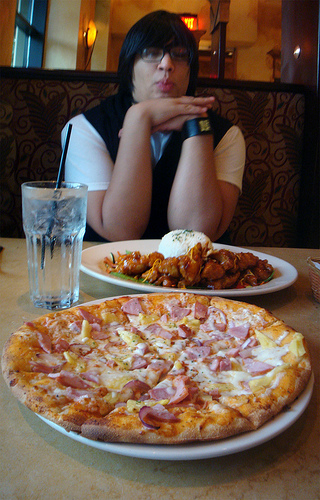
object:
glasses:
[138, 42, 193, 63]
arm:
[59, 103, 152, 233]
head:
[119, 9, 195, 101]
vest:
[89, 106, 120, 135]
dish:
[80, 247, 205, 299]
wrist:
[114, 106, 154, 128]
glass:
[36, 282, 51, 310]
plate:
[65, 236, 299, 295]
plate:
[2, 292, 315, 461]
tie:
[150, 133, 171, 167]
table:
[18, 467, 307, 495]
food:
[125, 244, 151, 281]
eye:
[142, 48, 161, 60]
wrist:
[172, 117, 217, 140]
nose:
[158, 52, 174, 72]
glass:
[23, 180, 89, 215]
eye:
[167, 52, 191, 65]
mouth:
[154, 77, 172, 92]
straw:
[50, 121, 73, 189]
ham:
[138, 320, 178, 341]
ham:
[245, 354, 273, 374]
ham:
[54, 368, 90, 387]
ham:
[128, 351, 144, 369]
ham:
[121, 295, 145, 314]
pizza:
[0, 291, 309, 445]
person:
[62, 9, 243, 241]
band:
[181, 120, 210, 142]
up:
[153, 77, 185, 120]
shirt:
[55, 101, 246, 195]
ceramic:
[67, 432, 111, 454]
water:
[29, 278, 81, 295]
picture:
[0, 0, 320, 498]